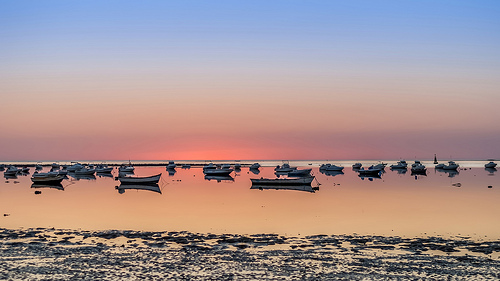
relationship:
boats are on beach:
[117, 173, 166, 187] [99, 198, 119, 211]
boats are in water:
[117, 173, 166, 187] [237, 199, 267, 211]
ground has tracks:
[137, 240, 173, 270] [178, 240, 205, 264]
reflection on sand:
[393, 215, 424, 230] [106, 205, 131, 216]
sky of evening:
[122, 15, 166, 47] [228, 144, 243, 145]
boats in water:
[117, 173, 166, 187] [237, 199, 267, 211]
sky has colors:
[122, 15, 166, 47] [336, 82, 352, 140]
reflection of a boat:
[393, 215, 424, 230] [24, 171, 67, 180]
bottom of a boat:
[247, 181, 315, 190] [24, 171, 67, 180]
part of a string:
[311, 176, 327, 192] [316, 175, 323, 188]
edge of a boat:
[363, 171, 372, 175] [24, 171, 67, 180]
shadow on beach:
[249, 184, 316, 194] [99, 198, 119, 211]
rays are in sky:
[205, 103, 231, 135] [122, 15, 166, 47]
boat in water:
[24, 171, 67, 180] [237, 199, 267, 211]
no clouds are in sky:
[409, 20, 444, 46] [122, 15, 166, 47]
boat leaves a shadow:
[24, 171, 67, 180] [249, 184, 316, 194]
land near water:
[354, 222, 405, 250] [237, 199, 267, 211]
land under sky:
[354, 222, 405, 250] [122, 15, 166, 47]